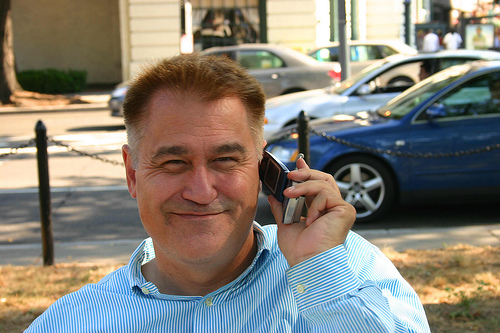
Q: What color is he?
A: White.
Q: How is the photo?
A: Clear.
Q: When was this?
A: Daytime.